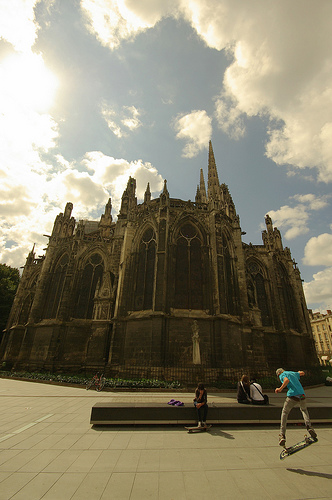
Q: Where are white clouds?
A: In the sky.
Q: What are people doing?
A: Skateboarding.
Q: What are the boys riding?
A: Skateboards.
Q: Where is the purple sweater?
A: On the ground.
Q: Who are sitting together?
A: A couple.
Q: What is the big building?
A: A church.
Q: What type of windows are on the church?
A: Stained glass.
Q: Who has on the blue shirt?
A: A man.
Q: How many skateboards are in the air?
A: One.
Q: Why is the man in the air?
A: Skateboard trick.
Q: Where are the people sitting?
A: Bench.